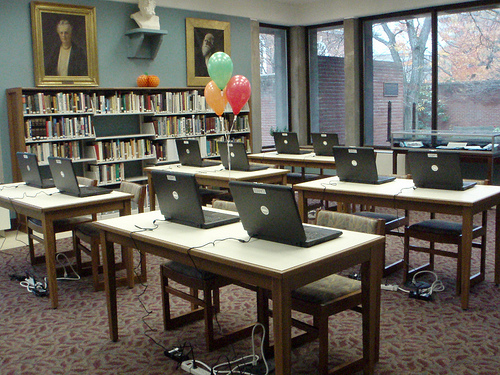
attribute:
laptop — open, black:
[148, 171, 234, 228]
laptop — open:
[229, 180, 339, 248]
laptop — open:
[49, 157, 117, 197]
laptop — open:
[18, 153, 50, 188]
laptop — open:
[335, 147, 399, 185]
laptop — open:
[407, 147, 485, 190]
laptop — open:
[176, 137, 209, 167]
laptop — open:
[221, 141, 269, 170]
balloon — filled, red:
[227, 74, 251, 113]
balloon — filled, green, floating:
[206, 51, 235, 93]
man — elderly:
[53, 19, 84, 76]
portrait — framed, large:
[29, 1, 99, 90]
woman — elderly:
[199, 33, 215, 56]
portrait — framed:
[184, 16, 231, 88]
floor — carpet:
[2, 179, 497, 372]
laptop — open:
[273, 130, 303, 151]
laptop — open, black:
[314, 131, 349, 153]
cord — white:
[251, 323, 268, 373]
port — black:
[166, 346, 187, 360]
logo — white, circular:
[257, 204, 271, 217]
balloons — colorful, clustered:
[201, 52, 251, 120]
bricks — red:
[319, 57, 342, 134]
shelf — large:
[6, 84, 158, 230]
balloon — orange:
[204, 81, 228, 116]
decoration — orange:
[135, 73, 159, 88]